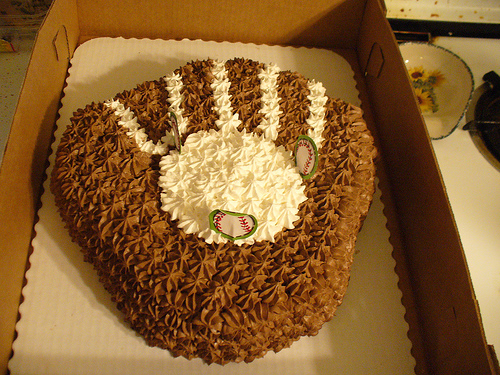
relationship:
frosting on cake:
[48, 56, 381, 361] [50, 54, 377, 366]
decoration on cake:
[170, 109, 181, 150] [50, 54, 377, 366]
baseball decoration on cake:
[292, 136, 319, 180] [50, 54, 377, 366]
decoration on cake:
[209, 211, 257, 242] [50, 54, 377, 366]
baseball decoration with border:
[292, 136, 319, 180] [66, 33, 376, 348]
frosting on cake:
[48, 56, 380, 367] [50, 54, 377, 366]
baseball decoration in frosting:
[292, 136, 319, 180] [75, 60, 381, 337]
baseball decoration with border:
[291, 134, 316, 180] [311, 138, 317, 181]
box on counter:
[0, 2, 498, 374] [391, 26, 498, 366]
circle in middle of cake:
[156, 120, 310, 243] [33, 47, 420, 371]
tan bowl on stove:
[397, 38, 476, 133] [431, 31, 496, 371]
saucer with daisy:
[388, 40, 474, 140] [420, 65, 446, 90]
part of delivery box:
[30, 72, 52, 123] [0, 0, 497, 373]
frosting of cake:
[48, 56, 381, 361] [50, 54, 377, 366]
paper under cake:
[15, 22, 415, 374] [58, 40, 398, 358]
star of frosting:
[220, 110, 242, 135] [48, 56, 381, 361]